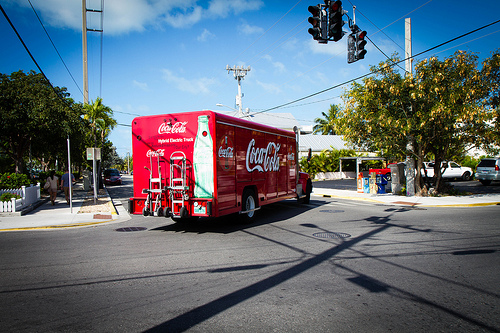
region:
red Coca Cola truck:
[129, 109, 314, 227]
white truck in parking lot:
[418, 158, 473, 178]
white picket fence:
[2, 178, 40, 213]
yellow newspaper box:
[368, 173, 379, 194]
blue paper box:
[361, 176, 369, 193]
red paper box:
[355, 172, 362, 191]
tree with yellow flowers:
[316, 51, 498, 196]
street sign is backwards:
[84, 144, 101, 201]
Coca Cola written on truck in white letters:
[245, 135, 281, 173]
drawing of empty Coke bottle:
[192, 113, 214, 195]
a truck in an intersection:
[67, 63, 410, 292]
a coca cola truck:
[117, 87, 353, 232]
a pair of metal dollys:
[126, 146, 212, 228]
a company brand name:
[235, 126, 297, 185]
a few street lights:
[291, 0, 383, 79]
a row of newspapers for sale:
[348, 164, 394, 195]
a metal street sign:
[79, 141, 123, 221]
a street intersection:
[100, 179, 470, 331]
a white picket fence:
[7, 176, 48, 216]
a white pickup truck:
[399, 154, 479, 185]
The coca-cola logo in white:
[236, 136, 286, 174]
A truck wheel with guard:
[232, 185, 274, 224]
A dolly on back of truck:
[166, 144, 198, 221]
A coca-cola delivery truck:
[131, 104, 332, 226]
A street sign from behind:
[79, 140, 113, 197]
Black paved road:
[130, 255, 305, 298]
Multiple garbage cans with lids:
[356, 171, 408, 199]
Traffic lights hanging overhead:
[293, 9, 375, 59]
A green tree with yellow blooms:
[318, 73, 492, 180]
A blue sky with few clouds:
[123, 15, 221, 93]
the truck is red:
[122, 118, 334, 258]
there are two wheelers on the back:
[131, 161, 201, 229]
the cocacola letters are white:
[232, 141, 300, 177]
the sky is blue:
[121, 36, 308, 82]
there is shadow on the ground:
[277, 228, 409, 309]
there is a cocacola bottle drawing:
[185, 120, 217, 201]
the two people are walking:
[49, 160, 94, 215]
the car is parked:
[100, 157, 135, 196]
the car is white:
[423, 155, 481, 198]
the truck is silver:
[469, 156, 497, 188]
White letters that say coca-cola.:
[221, 131, 303, 197]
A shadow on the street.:
[126, 191, 415, 331]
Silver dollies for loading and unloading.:
[111, 142, 203, 261]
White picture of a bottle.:
[181, 95, 228, 232]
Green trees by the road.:
[316, 42, 489, 224]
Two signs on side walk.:
[54, 132, 106, 225]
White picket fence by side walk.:
[0, 158, 52, 224]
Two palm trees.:
[76, 76, 126, 142]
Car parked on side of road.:
[100, 145, 125, 210]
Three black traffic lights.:
[281, 4, 388, 68]